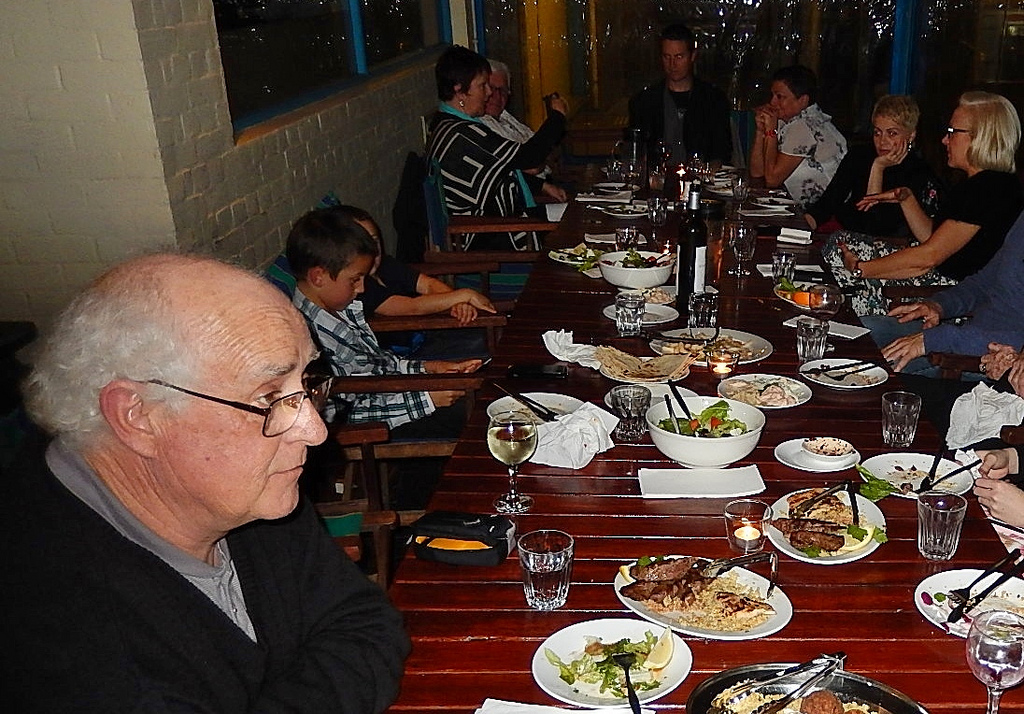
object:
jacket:
[0, 437, 417, 707]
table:
[298, 143, 1016, 712]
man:
[8, 254, 418, 711]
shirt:
[427, 105, 564, 248]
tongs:
[699, 646, 838, 710]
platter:
[673, 637, 927, 709]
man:
[595, 12, 753, 164]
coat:
[625, 90, 753, 164]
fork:
[917, 553, 991, 593]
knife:
[939, 572, 1022, 624]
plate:
[917, 550, 1023, 658]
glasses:
[151, 362, 349, 427]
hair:
[5, 246, 202, 433]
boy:
[302, 215, 477, 427]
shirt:
[318, 303, 479, 427]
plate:
[759, 479, 906, 572]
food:
[759, 479, 865, 566]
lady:
[882, 85, 1022, 279]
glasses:
[948, 120, 1022, 150]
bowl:
[651, 392, 757, 463]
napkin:
[641, 464, 765, 491]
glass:
[523, 529, 584, 623]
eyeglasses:
[176, 356, 348, 432]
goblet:
[487, 395, 541, 516]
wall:
[28, 3, 468, 309]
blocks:
[28, 3, 215, 279]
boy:
[262, 207, 385, 374]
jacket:
[284, 290, 431, 426]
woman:
[822, 93, 939, 256]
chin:
[859, 148, 914, 177]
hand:
[885, 148, 913, 169]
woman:
[855, 104, 1020, 339]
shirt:
[936, 154, 1004, 273]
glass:
[477, 402, 554, 517]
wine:
[477, 417, 538, 463]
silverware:
[608, 645, 651, 712]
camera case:
[399, 512, 512, 571]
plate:
[613, 556, 797, 643]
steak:
[622, 544, 694, 601]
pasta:
[663, 574, 780, 632]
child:
[276, 209, 482, 447]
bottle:
[676, 187, 712, 311]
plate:
[529, 615, 694, 709]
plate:
[907, 571, 1022, 643]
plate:
[857, 450, 977, 505]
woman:
[414, 40, 576, 254]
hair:
[952, 87, 1021, 176]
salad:
[663, 399, 746, 434]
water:
[518, 561, 568, 596]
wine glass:
[477, 397, 542, 523]